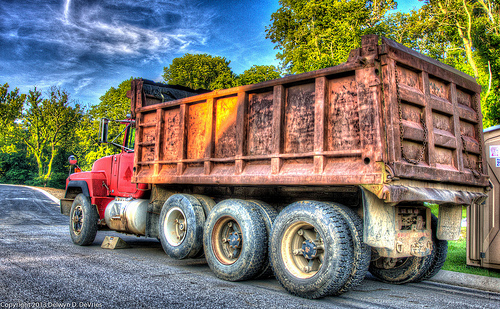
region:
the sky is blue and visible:
[46, 33, 109, 43]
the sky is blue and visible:
[41, 22, 146, 95]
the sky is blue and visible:
[58, 8, 269, 90]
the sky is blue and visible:
[39, 3, 240, 154]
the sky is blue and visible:
[44, 23, 206, 68]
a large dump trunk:
[54, 47, 490, 299]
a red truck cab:
[61, 126, 142, 246]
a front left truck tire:
[65, 193, 95, 246]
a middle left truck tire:
[159, 193, 206, 263]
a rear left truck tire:
[204, 198, 259, 282]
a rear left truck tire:
[274, 195, 348, 298]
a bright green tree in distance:
[21, 90, 70, 184]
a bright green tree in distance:
[0, 88, 22, 166]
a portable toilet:
[457, 122, 498, 270]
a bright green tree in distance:
[266, 1, 380, 58]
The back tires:
[163, 203, 345, 292]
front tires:
[58, 201, 101, 233]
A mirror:
[68, 143, 80, 165]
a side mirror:
[97, 116, 116, 141]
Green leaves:
[402, 13, 456, 55]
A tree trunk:
[455, 33, 482, 63]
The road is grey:
[15, 226, 75, 301]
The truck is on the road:
[58, 71, 448, 287]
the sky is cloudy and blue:
[42, 16, 189, 64]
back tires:
[391, 261, 438, 278]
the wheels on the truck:
[60, 189, 449, 298]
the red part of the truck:
[58, 108, 146, 237]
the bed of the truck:
[122, 35, 488, 202]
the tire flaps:
[342, 193, 464, 255]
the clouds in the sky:
[6, 2, 179, 60]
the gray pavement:
[6, 227, 71, 281]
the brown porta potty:
[462, 117, 498, 264]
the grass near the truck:
[447, 242, 464, 270]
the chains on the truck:
[389, 59, 486, 180]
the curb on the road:
[23, 180, 51, 206]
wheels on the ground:
[183, 193, 340, 280]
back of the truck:
[353, 61, 484, 192]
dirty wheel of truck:
[279, 208, 348, 273]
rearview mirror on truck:
[86, 106, 126, 151]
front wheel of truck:
[56, 184, 107, 249]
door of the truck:
[106, 148, 138, 194]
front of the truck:
[54, 147, 106, 207]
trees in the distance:
[12, 86, 72, 151]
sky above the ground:
[57, 7, 147, 73]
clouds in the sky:
[36, 12, 133, 80]